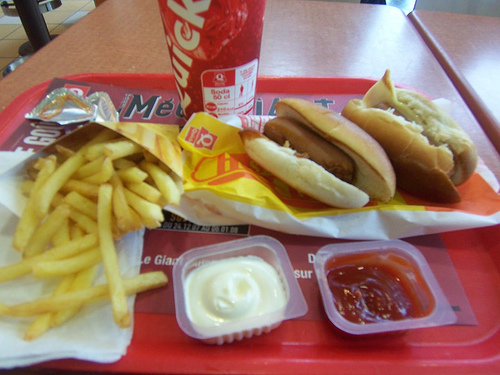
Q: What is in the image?
A: Fries.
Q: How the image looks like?
A: Yummy.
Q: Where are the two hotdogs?
A: On the red tray.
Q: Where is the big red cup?
A: On the tray.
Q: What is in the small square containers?
A: Ketchup and mayo.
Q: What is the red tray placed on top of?
A: A brown table.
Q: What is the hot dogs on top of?
A: A yellow and orange bag.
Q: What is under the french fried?
A: White napkins.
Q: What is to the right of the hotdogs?
A: Fries.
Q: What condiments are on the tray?
A: Ketchup and mayo.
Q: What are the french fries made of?
A: Potatoes.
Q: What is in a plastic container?
A: Ketchup.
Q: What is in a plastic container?
A: Mayonnaise.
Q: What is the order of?
A: French fries.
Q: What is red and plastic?
A: A tray.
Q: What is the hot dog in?
A: A bun.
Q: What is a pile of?
A: Napkins.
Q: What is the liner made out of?
A: Paper.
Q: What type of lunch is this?
A: Fast food.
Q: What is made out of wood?
A: The table.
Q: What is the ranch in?
A: A container.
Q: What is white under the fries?
A: Napkin.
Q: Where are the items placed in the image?
A: Tray.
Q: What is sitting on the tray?
A: Beverage.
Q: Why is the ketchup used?
A: Dip.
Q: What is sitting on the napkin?
A: Fries.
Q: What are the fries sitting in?
A: A small yellow bag.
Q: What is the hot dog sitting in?
A: A bun.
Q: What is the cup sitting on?
A: The tray.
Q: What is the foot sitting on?
A: On a tray.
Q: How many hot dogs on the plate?
A: 2.